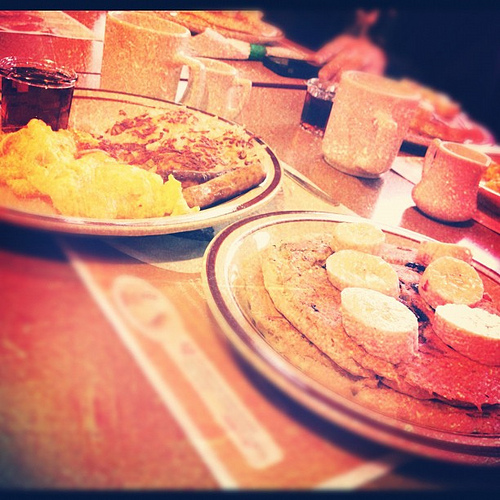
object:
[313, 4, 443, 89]
people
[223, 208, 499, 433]
pancake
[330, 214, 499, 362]
bananas